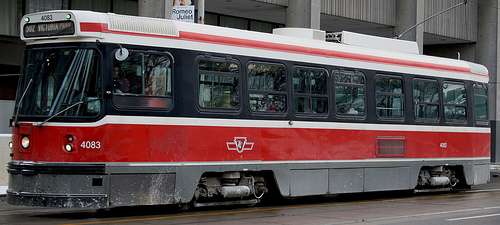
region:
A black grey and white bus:
[24, 16, 494, 195]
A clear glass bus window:
[188, 57, 234, 110]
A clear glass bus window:
[240, 57, 286, 117]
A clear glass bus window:
[292, 64, 332, 124]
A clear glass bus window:
[325, 62, 367, 119]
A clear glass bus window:
[369, 79, 408, 125]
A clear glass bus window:
[415, 70, 445, 127]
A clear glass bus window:
[445, 84, 471, 130]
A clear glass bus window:
[469, 80, 491, 117]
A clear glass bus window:
[110, 51, 183, 103]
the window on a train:
[105, 47, 182, 114]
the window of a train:
[189, 50, 246, 116]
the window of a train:
[244, 58, 292, 125]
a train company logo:
[218, 134, 264, 155]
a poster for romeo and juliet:
[168, 0, 200, 25]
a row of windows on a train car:
[105, 42, 491, 130]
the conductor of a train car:
[104, 65, 132, 106]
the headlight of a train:
[12, 132, 34, 149]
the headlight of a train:
[57, 130, 82, 152]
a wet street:
[387, 198, 492, 223]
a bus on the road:
[4, 8, 499, 201]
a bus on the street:
[19, 1, 288, 211]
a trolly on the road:
[7, 1, 385, 222]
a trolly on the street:
[10, 16, 395, 223]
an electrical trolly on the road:
[19, 11, 352, 224]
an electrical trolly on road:
[60, 8, 332, 218]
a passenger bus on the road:
[79, 16, 480, 221]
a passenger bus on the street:
[97, 22, 496, 179]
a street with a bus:
[47, 22, 456, 223]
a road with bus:
[151, 30, 412, 220]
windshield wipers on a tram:
[9, 73, 84, 128]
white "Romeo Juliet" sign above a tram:
[168, 3, 195, 21]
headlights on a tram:
[5, 131, 85, 156]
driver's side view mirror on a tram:
[111, 38, 130, 60]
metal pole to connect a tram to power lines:
[393, 0, 469, 40]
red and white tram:
[5, 4, 492, 171]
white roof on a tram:
[45, 8, 490, 75]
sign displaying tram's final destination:
[17, 18, 75, 38]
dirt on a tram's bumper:
[6, 169, 193, 210]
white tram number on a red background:
[77, 140, 103, 149]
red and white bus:
[6, 10, 494, 215]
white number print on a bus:
[75, 138, 102, 150]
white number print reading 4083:
[77, 138, 102, 148]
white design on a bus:
[221, 134, 257, 153]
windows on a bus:
[96, 41, 492, 129]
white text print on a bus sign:
[17, 18, 69, 36]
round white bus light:
[16, 134, 33, 148]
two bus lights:
[56, 131, 76, 154]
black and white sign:
[166, 3, 196, 20]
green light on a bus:
[60, 11, 71, 21]